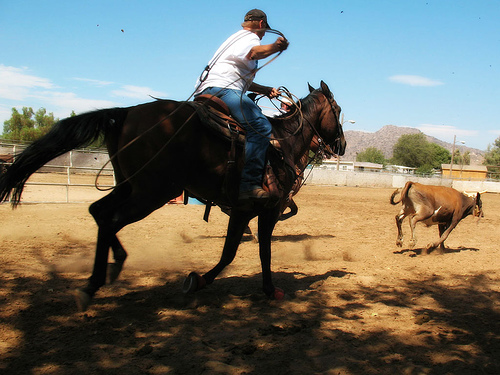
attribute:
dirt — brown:
[325, 262, 385, 307]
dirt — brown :
[3, 157, 498, 372]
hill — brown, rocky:
[343, 126, 490, 162]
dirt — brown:
[3, 186, 497, 373]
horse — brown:
[2, 78, 347, 311]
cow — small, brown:
[386, 179, 485, 256]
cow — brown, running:
[387, 184, 483, 250]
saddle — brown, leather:
[197, 91, 298, 222]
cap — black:
[244, 8, 272, 29]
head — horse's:
[314, 80, 348, 154]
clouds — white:
[2, 67, 129, 134]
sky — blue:
[2, 2, 497, 174]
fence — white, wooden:
[307, 166, 494, 195]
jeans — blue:
[196, 84, 267, 189]